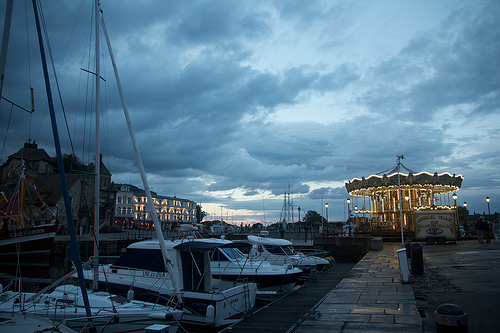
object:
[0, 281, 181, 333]
boat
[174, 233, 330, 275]
boat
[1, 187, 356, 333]
harbor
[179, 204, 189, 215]
light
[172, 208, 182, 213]
light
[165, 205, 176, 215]
light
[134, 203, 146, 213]
light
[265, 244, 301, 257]
window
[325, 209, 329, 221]
lit post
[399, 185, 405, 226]
lit post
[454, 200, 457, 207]
lit post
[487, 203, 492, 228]
lit post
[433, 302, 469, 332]
bin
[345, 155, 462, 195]
roof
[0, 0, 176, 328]
boat masts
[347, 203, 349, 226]
pole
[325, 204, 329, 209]
light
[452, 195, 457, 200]
light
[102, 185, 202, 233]
building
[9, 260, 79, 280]
water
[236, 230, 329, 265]
white boat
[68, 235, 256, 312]
white boat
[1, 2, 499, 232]
sky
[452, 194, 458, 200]
light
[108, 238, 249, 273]
cabin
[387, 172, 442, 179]
lights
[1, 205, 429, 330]
pier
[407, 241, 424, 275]
trash can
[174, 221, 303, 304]
boat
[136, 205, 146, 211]
lights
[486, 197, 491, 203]
light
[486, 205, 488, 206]
pole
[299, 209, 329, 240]
tree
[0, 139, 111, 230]
buildings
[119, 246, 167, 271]
window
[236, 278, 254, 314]
ladder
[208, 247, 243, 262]
window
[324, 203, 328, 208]
lights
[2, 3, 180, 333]
sail gear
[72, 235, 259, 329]
boat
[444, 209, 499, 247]
people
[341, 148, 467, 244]
building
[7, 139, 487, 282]
shore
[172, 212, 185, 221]
lights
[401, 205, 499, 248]
distance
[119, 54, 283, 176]
clouds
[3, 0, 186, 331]
mast